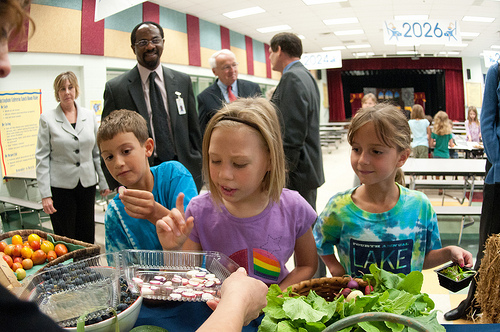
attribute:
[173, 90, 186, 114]
badge — white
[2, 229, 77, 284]
tomatoes — unripe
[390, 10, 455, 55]
2026 — on lunchroom wall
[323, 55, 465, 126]
curtains — red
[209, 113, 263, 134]
head band — black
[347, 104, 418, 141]
hair — blonde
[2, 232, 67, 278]
tomatoes — small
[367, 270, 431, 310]
spinach leaves — green, crisp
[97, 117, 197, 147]
hair — brown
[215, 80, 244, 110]
tie — red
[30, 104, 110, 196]
shirt — dress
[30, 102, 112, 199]
jacket — white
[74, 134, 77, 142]
buttons — large, black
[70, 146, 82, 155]
buttons — large, black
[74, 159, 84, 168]
buttons — large, black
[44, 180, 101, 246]
skirt — black